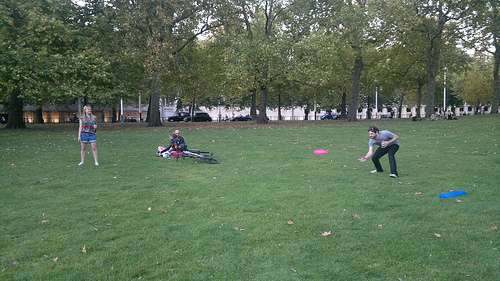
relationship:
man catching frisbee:
[347, 124, 449, 218] [295, 133, 340, 175]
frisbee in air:
[290, 126, 338, 169] [305, 127, 344, 192]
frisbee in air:
[280, 129, 331, 164] [274, 126, 385, 226]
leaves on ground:
[287, 207, 341, 243] [272, 211, 377, 260]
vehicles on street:
[160, 109, 244, 145] [120, 95, 258, 126]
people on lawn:
[48, 92, 485, 221] [143, 164, 413, 239]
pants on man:
[365, 144, 433, 197] [353, 104, 427, 193]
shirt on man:
[357, 126, 410, 158] [350, 107, 407, 201]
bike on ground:
[184, 144, 240, 178] [181, 203, 309, 243]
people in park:
[54, 103, 410, 187] [178, 179, 318, 235]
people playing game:
[62, 96, 412, 186] [58, 94, 483, 217]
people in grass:
[54, 103, 410, 187] [5, 115, 498, 279]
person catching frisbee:
[341, 122, 411, 188] [304, 144, 337, 163]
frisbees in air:
[304, 142, 475, 222] [18, 36, 475, 241]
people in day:
[54, 103, 410, 187] [8, 3, 492, 280]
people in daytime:
[50, 97, 422, 201] [4, 5, 494, 278]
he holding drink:
[350, 115, 431, 200] [375, 136, 395, 152]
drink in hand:
[375, 136, 395, 152] [348, 153, 378, 176]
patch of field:
[195, 199, 316, 239] [4, 111, 498, 279]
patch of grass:
[82, 191, 224, 251] [5, 115, 498, 279]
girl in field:
[62, 98, 113, 171] [4, 111, 498, 279]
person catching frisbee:
[295, 118, 417, 204] [302, 139, 377, 172]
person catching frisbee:
[357, 117, 410, 183] [304, 138, 330, 175]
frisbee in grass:
[304, 138, 330, 175] [5, 115, 498, 279]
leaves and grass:
[289, 192, 374, 263] [5, 115, 498, 279]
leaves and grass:
[222, 204, 420, 260] [5, 115, 498, 279]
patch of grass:
[210, 209, 344, 254] [5, 115, 498, 279]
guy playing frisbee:
[339, 115, 426, 187] [304, 143, 329, 163]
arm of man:
[378, 127, 408, 153] [354, 119, 419, 177]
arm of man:
[354, 138, 384, 164] [348, 120, 408, 185]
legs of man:
[384, 150, 403, 182] [352, 120, 405, 183]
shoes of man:
[365, 166, 400, 179] [356, 123, 406, 188]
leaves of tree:
[302, 31, 329, 43] [305, 7, 379, 114]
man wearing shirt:
[357, 123, 406, 181] [366, 129, 395, 152]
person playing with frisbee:
[356, 120, 405, 180] [308, 142, 332, 160]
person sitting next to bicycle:
[168, 127, 185, 155] [154, 146, 214, 165]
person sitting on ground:
[168, 127, 185, 155] [0, 112, 499, 280]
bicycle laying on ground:
[154, 146, 214, 165] [0, 112, 499, 280]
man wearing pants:
[356, 125, 408, 183] [371, 139, 400, 179]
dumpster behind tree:
[1, 109, 8, 127] [0, 1, 129, 127]